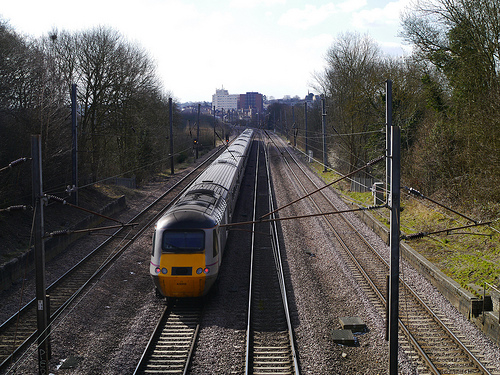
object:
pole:
[70, 83, 79, 207]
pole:
[168, 98, 175, 175]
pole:
[196, 103, 202, 159]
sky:
[2, 0, 487, 109]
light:
[193, 139, 199, 145]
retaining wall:
[24, 182, 122, 271]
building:
[237, 92, 264, 126]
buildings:
[262, 92, 324, 112]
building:
[211, 84, 240, 120]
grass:
[309, 159, 499, 312]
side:
[296, 0, 500, 375]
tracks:
[0, 131, 497, 372]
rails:
[259, 122, 500, 374]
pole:
[382, 78, 403, 374]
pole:
[320, 98, 329, 172]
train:
[149, 127, 254, 298]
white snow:
[145, 126, 252, 307]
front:
[149, 209, 222, 299]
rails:
[1, 109, 158, 371]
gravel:
[189, 269, 248, 375]